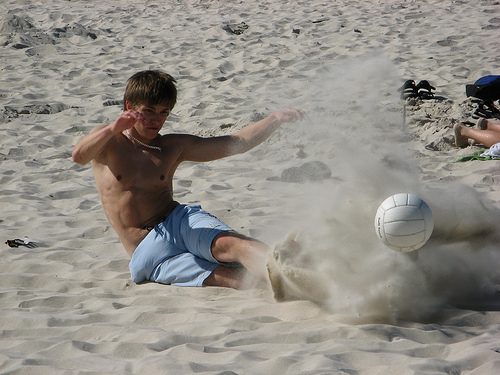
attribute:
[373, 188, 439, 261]
ball — white, round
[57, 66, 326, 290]
boy — white, sitting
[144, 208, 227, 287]
shorts — blue, brown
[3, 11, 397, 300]
sand — white, brown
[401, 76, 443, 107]
shoes — black, laying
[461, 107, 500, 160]
person — white, laying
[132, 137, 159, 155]
necklace — white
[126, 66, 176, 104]
hair — short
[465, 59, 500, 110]
bag — blue